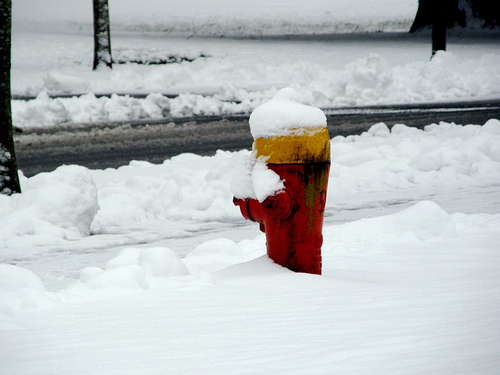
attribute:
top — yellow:
[253, 124, 335, 165]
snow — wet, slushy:
[24, 86, 257, 201]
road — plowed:
[38, 88, 499, 147]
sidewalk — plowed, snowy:
[23, 90, 497, 128]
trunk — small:
[93, 10, 125, 76]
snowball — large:
[29, 168, 89, 231]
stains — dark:
[290, 157, 335, 190]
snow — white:
[32, 230, 500, 371]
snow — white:
[248, 89, 325, 136]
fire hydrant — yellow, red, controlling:
[236, 124, 332, 277]